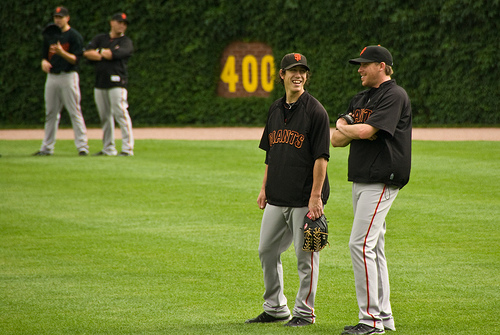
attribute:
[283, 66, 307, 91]
boy — smiling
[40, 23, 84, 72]
jersey — black, orange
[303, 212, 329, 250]
glove — black, leather, brown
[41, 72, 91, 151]
trousers — grey, gray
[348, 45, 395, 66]
cap — black, orange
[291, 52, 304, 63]
logo — orange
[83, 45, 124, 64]
arms — folded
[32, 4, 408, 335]
players — playing baseball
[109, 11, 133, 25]
cap — black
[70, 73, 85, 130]
stripe — red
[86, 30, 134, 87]
shirt — black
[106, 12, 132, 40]
head — turned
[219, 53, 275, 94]
number — yellow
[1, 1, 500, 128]
ivy — green, leafy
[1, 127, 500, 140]
warning track — brown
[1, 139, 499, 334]
grass — green, growing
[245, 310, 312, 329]
shoes — black